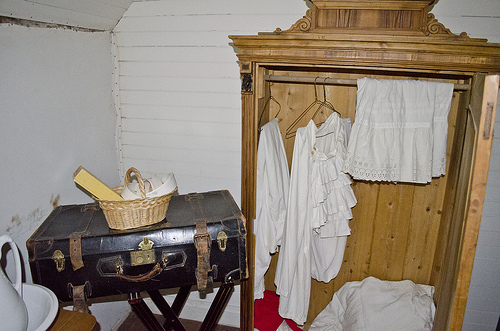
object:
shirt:
[272, 113, 358, 325]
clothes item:
[274, 111, 360, 325]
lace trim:
[309, 149, 359, 238]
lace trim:
[344, 157, 446, 182]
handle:
[111, 263, 161, 283]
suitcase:
[27, 190, 249, 302]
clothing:
[252, 70, 462, 329]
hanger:
[255, 66, 348, 144]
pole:
[245, 68, 482, 104]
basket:
[92, 169, 178, 231]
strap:
[61, 214, 88, 274]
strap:
[183, 196, 220, 293]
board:
[114, 12, 171, 63]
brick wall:
[114, 0, 499, 330]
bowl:
[13, 280, 67, 329]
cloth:
[343, 68, 455, 190]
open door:
[241, 59, 491, 313]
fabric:
[0, 19, 121, 278]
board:
[116, 43, 240, 62]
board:
[471, 290, 493, 326]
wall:
[470, 247, 497, 307]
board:
[122, 116, 239, 140]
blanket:
[314, 270, 441, 329]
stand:
[112, 287, 247, 328]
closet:
[225, 0, 491, 330]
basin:
[1, 231, 40, 329]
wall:
[1, 14, 130, 329]